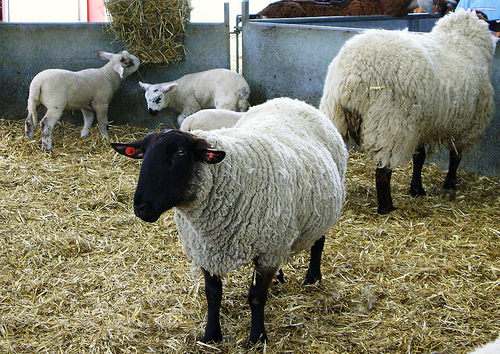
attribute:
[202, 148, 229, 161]
left ear — sheep's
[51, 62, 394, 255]
sheep — white, marker, pen, legs, black, fleece, dirty, wool, short, ear, leg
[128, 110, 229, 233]
head — black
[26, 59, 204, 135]
lambs — white, smell, nose, small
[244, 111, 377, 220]
coat — thick